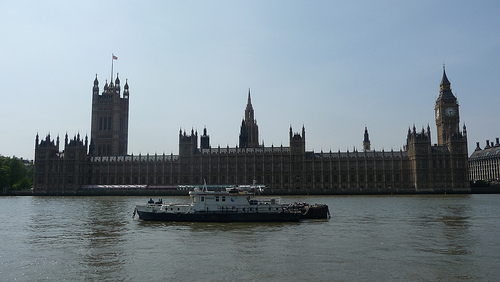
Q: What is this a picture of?
A: Boat.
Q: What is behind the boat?
A: Building.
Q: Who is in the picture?
A: No one.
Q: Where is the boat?
A: On the water.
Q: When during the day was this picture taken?
A: Daytime.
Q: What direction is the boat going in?
A: Right.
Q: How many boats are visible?
A: One.